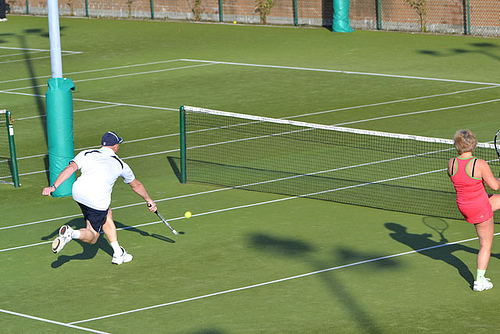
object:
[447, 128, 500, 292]
woman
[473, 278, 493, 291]
shoes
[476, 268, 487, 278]
socks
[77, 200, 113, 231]
shorts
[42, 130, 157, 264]
man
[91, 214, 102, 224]
blue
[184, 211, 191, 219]
ball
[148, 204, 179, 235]
racket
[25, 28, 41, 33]
shadow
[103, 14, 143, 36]
ground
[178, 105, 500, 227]
net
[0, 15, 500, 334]
court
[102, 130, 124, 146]
hat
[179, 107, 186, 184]
pole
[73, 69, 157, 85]
line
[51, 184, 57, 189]
watch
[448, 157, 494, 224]
outfit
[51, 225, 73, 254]
foot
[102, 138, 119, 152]
head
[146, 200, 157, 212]
hand